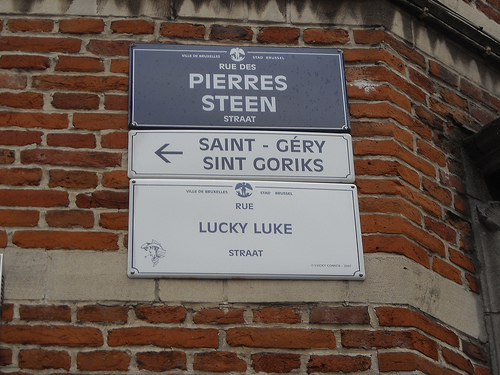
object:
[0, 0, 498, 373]
building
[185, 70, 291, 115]
lettering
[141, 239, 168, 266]
logo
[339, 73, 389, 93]
discoloration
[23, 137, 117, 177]
bricks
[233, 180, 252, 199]
emblem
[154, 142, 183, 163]
arrow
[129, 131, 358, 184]
borders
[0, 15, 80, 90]
brick siding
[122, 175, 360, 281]
signs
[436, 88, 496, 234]
edge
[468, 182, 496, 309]
window frame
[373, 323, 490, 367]
brick wall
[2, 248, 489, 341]
cement line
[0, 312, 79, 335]
bricks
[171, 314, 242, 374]
bricks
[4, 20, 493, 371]
wall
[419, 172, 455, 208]
brick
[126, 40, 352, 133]
border